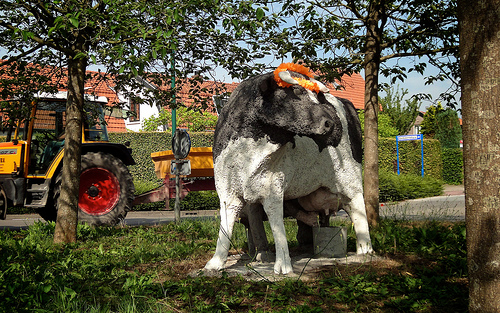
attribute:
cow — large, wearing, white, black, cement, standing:
[178, 56, 376, 251]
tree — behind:
[68, 26, 171, 85]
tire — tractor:
[47, 135, 148, 233]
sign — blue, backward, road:
[386, 118, 436, 146]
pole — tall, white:
[160, 47, 192, 232]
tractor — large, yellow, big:
[2, 74, 139, 233]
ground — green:
[91, 230, 163, 279]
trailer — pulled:
[143, 142, 202, 213]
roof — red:
[125, 85, 172, 120]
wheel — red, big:
[81, 172, 121, 211]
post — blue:
[364, 120, 425, 228]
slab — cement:
[403, 195, 451, 235]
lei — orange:
[262, 55, 312, 101]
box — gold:
[153, 151, 181, 181]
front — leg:
[172, 177, 301, 257]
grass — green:
[76, 239, 154, 286]